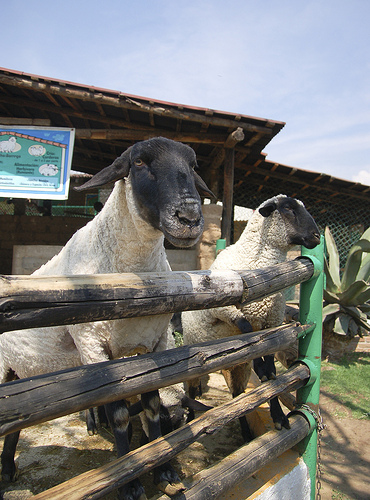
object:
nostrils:
[179, 217, 200, 228]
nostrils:
[314, 233, 320, 240]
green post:
[296, 233, 325, 498]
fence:
[0, 255, 315, 500]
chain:
[294, 402, 327, 500]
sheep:
[86, 381, 214, 447]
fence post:
[0, 319, 304, 436]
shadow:
[320, 390, 369, 499]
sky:
[272, 23, 368, 72]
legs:
[66, 321, 135, 458]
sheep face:
[160, 401, 191, 437]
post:
[214, 239, 226, 258]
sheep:
[0, 136, 218, 500]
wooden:
[252, 273, 280, 288]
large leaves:
[324, 226, 340, 287]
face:
[278, 198, 322, 250]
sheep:
[182, 194, 320, 443]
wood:
[65, 370, 121, 401]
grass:
[326, 351, 370, 404]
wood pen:
[80, 128, 118, 141]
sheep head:
[128, 136, 206, 248]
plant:
[323, 225, 368, 336]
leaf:
[339, 239, 370, 293]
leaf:
[345, 306, 368, 322]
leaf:
[359, 226, 370, 242]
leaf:
[336, 280, 367, 304]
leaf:
[323, 288, 340, 303]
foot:
[153, 464, 187, 496]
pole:
[153, 415, 309, 499]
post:
[30, 361, 309, 500]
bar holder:
[0, 257, 313, 335]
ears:
[191, 167, 218, 200]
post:
[0, 259, 314, 336]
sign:
[0, 124, 76, 200]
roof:
[0, 64, 285, 127]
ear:
[73, 146, 132, 193]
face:
[132, 136, 206, 249]